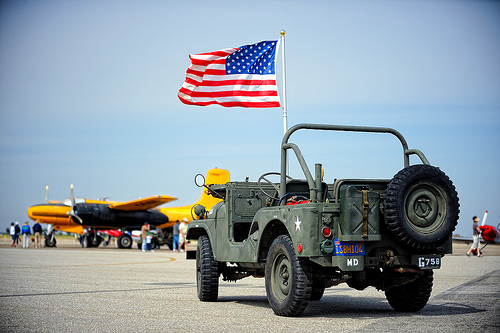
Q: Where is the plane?
A: Grounded.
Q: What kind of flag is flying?
A: American.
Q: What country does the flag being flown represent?
A: USA.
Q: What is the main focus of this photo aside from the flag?
A: An army jeep.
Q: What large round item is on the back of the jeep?
A: Spare tire.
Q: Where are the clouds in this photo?
A: Non-existent.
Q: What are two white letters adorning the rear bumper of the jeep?
A: MD.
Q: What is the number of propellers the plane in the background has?
A: Two.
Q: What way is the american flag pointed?
A: Left.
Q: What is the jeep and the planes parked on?
A: Asphalt.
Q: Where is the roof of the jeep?
A: Non-existent.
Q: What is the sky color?
A: Blue.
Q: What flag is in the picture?
A: American flag.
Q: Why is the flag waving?
A: Windy.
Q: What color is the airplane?
A: Black and yellow.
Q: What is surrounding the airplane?
A: People.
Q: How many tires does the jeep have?
A: Five.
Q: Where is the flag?
A: Middle.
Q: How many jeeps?
A: One.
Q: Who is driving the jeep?
A: No one.